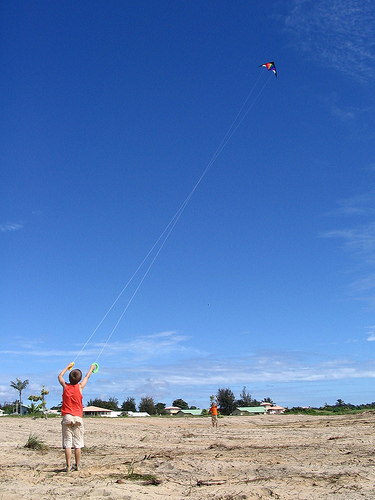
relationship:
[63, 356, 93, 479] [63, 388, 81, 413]
person has shirt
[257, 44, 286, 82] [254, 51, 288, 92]
kite in sky